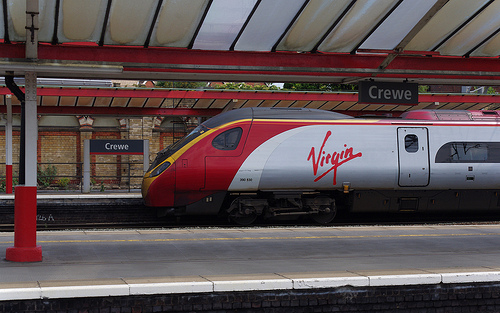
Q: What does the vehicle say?
A: Virgin.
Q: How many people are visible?
A: None.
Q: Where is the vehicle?
A: At a train station.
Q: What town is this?
A: Crewe.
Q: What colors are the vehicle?
A: Black, yellow, red, and white.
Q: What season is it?
A: Summer.